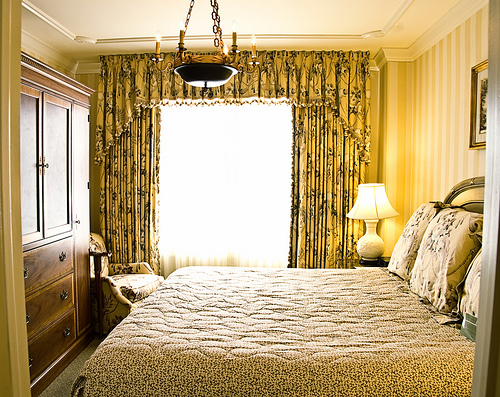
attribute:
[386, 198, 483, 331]
pillows — gold, black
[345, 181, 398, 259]
lamp — white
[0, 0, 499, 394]
room — sunlit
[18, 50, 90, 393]
chest — brown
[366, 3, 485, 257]
wall paper — striped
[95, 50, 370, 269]
curtains — nice, decorative, yellow, black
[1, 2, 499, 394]
bedroom — fancy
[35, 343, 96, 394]
rug — green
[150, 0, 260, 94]
light — black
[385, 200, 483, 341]
pillow cases — decorative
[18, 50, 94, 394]
dresser — lovely, wood, stained, brown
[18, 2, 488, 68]
molding — decorative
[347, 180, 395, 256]
lamp — round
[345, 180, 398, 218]
lamp shade — dainty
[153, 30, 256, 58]
lights — candle-style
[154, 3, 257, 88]
ceiling light — black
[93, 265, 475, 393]
comforter — black, gold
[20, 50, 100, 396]
chest — brown, tall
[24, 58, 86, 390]
chest — three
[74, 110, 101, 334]
door — tall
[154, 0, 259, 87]
light — black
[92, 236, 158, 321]
chair — white, black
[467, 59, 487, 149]
frame — gold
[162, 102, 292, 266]
curtains — sheer, white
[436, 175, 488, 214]
headboard — gray, white